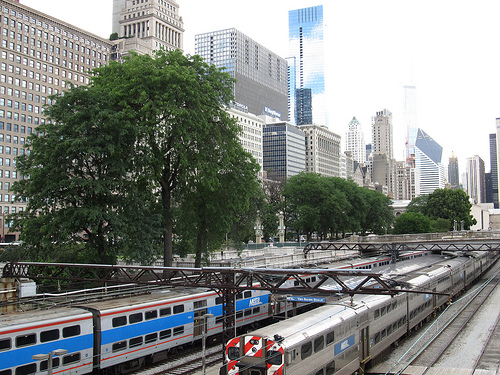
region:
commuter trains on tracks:
[11, 252, 493, 369]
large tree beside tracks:
[26, 51, 258, 287]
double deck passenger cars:
[21, 281, 319, 363]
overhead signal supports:
[19, 243, 405, 343]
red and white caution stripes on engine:
[218, 331, 299, 371]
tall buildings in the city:
[341, 100, 488, 203]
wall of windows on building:
[8, 10, 119, 261]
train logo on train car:
[233, 292, 275, 314]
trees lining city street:
[222, 176, 464, 237]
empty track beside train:
[414, 264, 494, 371]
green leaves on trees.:
[82, 96, 123, 213]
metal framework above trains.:
[110, 272, 357, 281]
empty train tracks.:
[455, 288, 487, 350]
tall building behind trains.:
[294, 22, 326, 125]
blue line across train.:
[105, 313, 191, 343]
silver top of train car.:
[277, 310, 334, 345]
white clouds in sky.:
[382, 16, 449, 52]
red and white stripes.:
[229, 340, 277, 364]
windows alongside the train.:
[299, 337, 339, 348]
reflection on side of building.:
[295, 31, 318, 83]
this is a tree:
[69, 88, 234, 246]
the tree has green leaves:
[88, 83, 175, 120]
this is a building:
[246, 63, 282, 118]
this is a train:
[301, 349, 328, 369]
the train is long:
[39, 297, 176, 326]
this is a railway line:
[446, 340, 483, 355]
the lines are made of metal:
[433, 349, 450, 364]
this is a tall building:
[243, 34, 264, 120]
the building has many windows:
[18, 15, 63, 77]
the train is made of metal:
[106, 312, 168, 329]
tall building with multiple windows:
[1, 0, 121, 236]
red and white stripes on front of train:
[222, 335, 282, 371]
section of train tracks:
[426, 330, 446, 361]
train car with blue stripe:
[75, 281, 276, 366]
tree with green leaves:
[76, 46, 231, 151]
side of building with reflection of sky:
[285, 0, 335, 126]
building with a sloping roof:
[412, 126, 442, 201]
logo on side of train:
[245, 295, 262, 302]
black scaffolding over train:
[140, 260, 420, 300]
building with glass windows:
[1, 1, 108, 186]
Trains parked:
[79, 210, 334, 372]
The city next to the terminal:
[7, 29, 433, 239]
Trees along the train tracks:
[45, 139, 287, 246]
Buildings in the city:
[229, 74, 391, 203]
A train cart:
[184, 313, 259, 368]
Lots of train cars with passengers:
[44, 248, 334, 330]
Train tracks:
[281, 214, 423, 366]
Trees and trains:
[402, 148, 484, 320]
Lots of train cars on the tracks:
[125, 238, 330, 372]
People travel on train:
[229, 254, 382, 364]